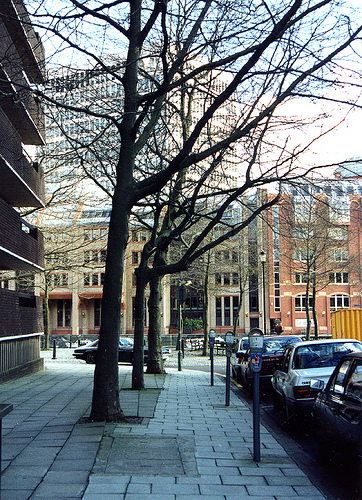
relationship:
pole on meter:
[251, 372, 263, 466] [246, 326, 264, 372]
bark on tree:
[103, 297, 114, 384] [2, 1, 360, 426]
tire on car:
[84, 350, 95, 365] [72, 333, 169, 365]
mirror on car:
[307, 374, 327, 393] [307, 349, 360, 455]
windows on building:
[293, 292, 316, 313] [264, 169, 360, 336]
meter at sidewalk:
[248, 327, 265, 463] [60, 362, 214, 489]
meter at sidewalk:
[248, 327, 265, 463] [171, 368, 253, 478]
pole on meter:
[252, 372, 260, 462] [245, 326, 267, 462]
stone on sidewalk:
[100, 433, 187, 478] [57, 366, 228, 498]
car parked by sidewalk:
[269, 338, 361, 430] [177, 378, 260, 470]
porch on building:
[2, 268, 46, 335] [2, 12, 44, 362]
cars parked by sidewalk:
[231, 333, 361, 398] [192, 372, 271, 475]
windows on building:
[271, 223, 349, 307] [260, 191, 361, 336]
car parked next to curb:
[309, 350, 361, 479] [228, 379, 315, 482]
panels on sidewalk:
[108, 433, 185, 475] [77, 392, 212, 494]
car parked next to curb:
[269, 338, 361, 430] [241, 396, 292, 436]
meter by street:
[244, 327, 269, 469] [198, 349, 359, 445]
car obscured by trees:
[72, 333, 169, 365] [84, 313, 168, 427]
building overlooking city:
[47, 57, 245, 187] [17, 195, 360, 324]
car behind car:
[309, 350, 361, 479] [269, 339, 361, 425]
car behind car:
[269, 339, 361, 425] [240, 331, 303, 388]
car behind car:
[240, 331, 303, 388] [230, 337, 247, 381]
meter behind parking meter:
[248, 327, 265, 463] [223, 330, 236, 405]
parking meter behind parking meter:
[223, 330, 236, 405] [206, 328, 217, 387]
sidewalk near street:
[0, 363, 327, 498] [45, 344, 227, 374]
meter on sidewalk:
[248, 327, 265, 463] [0, 363, 327, 498]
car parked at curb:
[269, 339, 361, 425] [205, 370, 337, 499]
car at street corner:
[72, 336, 171, 366] [53, 346, 227, 374]